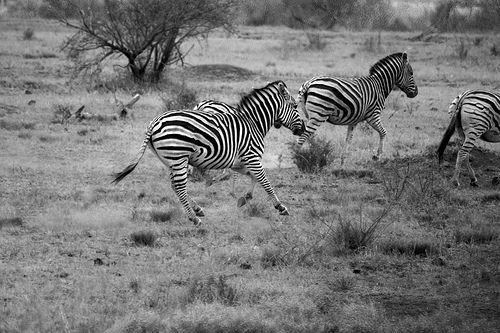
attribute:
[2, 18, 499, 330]
grass — patches 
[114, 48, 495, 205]
zebras — running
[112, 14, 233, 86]
tree — small 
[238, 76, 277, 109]
hair — zebras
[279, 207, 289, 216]
hoof — black 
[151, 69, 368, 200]
zebras — running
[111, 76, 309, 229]
zebra — jumping up, several, running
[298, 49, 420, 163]
zebra — running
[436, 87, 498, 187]
zebra — running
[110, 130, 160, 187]
tail — black, bushy 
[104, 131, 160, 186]
tail — long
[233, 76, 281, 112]
mane — black 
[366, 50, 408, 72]
mane — black , white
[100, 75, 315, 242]
zebra — white, black, striped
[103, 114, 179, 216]
tail — small 